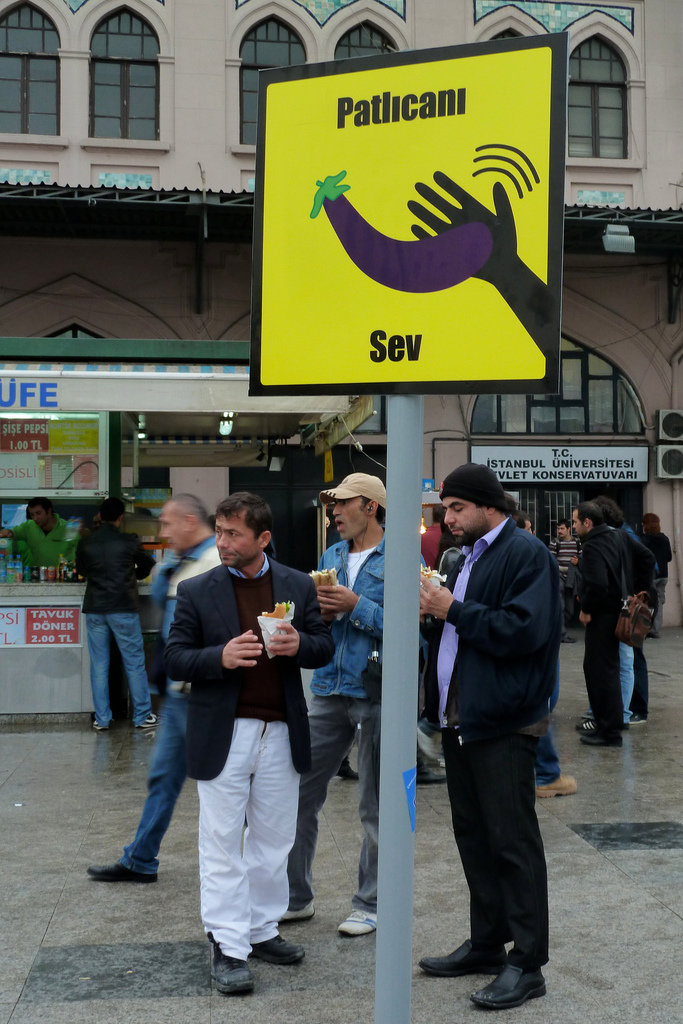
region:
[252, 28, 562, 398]
yellow sign with a picture of an eggplant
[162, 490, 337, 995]
man holding a sandwich in white paper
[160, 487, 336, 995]
man wearing white pants and black jacket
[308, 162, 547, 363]
black arm behind an eggplant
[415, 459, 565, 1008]
man looking down at a sandwich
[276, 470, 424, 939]
man in tan hat holding a sandwich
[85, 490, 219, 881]
man walking on the sidewalk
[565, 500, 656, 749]
man in black carrying brown briefcase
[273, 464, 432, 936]
man wearing a set of earphones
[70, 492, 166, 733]
man wearing black leather jacket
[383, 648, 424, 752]
a pole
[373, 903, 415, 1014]
the pole is grey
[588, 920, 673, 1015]
the ground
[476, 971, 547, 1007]
a black shoe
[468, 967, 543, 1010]
a shoe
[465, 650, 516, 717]
man is wearing a jacket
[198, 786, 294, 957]
white pants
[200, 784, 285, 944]
the man is wearing pants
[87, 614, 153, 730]
blue jeans the person is wearing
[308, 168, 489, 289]
the drawing of an eggplant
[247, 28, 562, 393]
the sign is yellow and black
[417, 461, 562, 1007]
the man is wearing a black cap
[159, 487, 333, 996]
the man is wearing white pants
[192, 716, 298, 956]
the pants are white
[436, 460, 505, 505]
the cap is black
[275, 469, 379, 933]
the man wearing a tan baseball cap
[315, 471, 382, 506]
the baseball cap is tan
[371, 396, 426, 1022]
the pole is metallic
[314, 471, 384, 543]
the head of the man in the tan baseball cap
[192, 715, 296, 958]
the white pants of a man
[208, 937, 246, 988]
the black shoe of a man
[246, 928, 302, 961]
the black shoe of a man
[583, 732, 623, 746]
the black shoe of a man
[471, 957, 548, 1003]
the black shoe of a man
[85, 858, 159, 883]
the black shoe of a man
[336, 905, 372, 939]
the white shoe of a man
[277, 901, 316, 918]
the white shoe of a man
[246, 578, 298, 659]
A man holding a sandwich in his hand.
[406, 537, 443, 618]
A man holding a sandwich in his hand.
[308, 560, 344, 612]
A man holding a sandwich in his hand.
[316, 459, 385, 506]
A man wearing a tan hat.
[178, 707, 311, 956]
A man wearing white pants.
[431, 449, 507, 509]
A man wearing a black hat.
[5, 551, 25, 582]
A few bottles on the counter.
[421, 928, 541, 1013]
A man wearing a pair of black shoes.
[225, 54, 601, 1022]
A tall metal pole with a sign attached to it.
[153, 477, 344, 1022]
man with white pants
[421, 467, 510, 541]
the head of a man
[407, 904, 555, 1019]
the shoes of a man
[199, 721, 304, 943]
the white pants of a man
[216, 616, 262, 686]
the hand of a man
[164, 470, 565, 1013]
men standing around eating on the sidewalk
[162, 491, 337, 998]
man wearing white pants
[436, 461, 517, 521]
black cap man is wearing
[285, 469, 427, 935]
man wearing a blue jacket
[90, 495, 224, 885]
man walking down the side walk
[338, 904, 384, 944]
white and blue tennis shoes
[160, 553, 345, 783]
black jacket man is wearing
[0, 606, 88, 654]
red and white sign in the distance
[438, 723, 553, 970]
black pants man is wearing